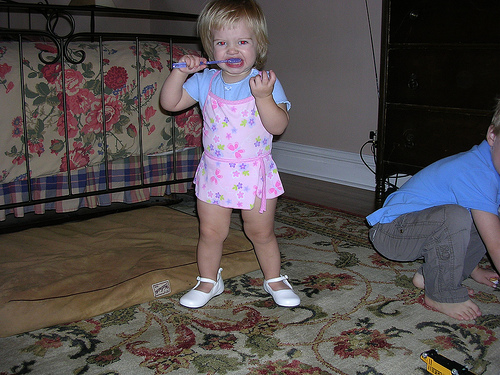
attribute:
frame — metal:
[0, 0, 207, 235]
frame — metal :
[2, 30, 231, 211]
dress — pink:
[185, 90, 287, 214]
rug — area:
[27, 187, 495, 374]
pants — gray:
[367, 204, 486, 302]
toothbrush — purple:
[171, 50, 243, 70]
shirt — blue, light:
[180, 67, 292, 109]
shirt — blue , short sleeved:
[365, 141, 498, 228]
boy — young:
[354, 91, 499, 335]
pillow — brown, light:
[4, 202, 262, 339]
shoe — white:
[162, 267, 236, 325]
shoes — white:
[160, 270, 324, 325]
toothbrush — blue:
[162, 54, 243, 69]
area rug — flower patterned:
[6, 193, 498, 365]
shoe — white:
[268, 269, 302, 309]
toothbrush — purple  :
[160, 0, 290, 130]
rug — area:
[2, 177, 497, 373]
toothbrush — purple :
[172, 57, 249, 72]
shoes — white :
[148, 258, 409, 367]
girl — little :
[156, 0, 323, 309]